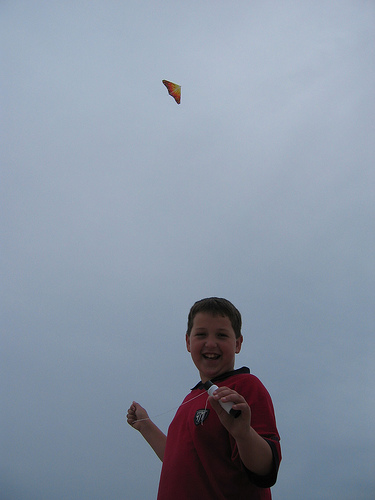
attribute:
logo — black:
[193, 405, 210, 431]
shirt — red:
[155, 367, 283, 499]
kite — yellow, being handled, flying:
[162, 78, 183, 105]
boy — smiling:
[127, 298, 282, 500]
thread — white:
[135, 384, 236, 423]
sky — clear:
[1, 6, 372, 492]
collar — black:
[190, 367, 251, 390]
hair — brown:
[187, 296, 242, 339]